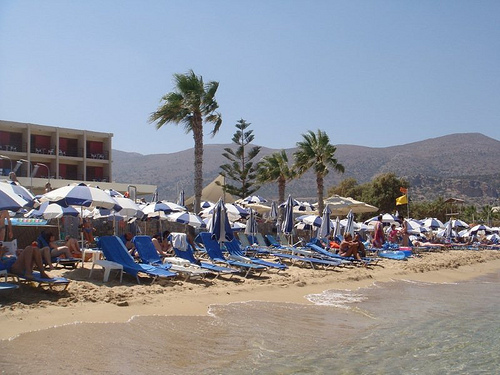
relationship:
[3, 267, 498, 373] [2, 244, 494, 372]
water on beach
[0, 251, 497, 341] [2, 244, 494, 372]
sand on beach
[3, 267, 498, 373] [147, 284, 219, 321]
water near sand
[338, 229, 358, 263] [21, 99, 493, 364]
person on beach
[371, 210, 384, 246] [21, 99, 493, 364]
person on beach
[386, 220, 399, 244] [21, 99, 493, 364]
person on beach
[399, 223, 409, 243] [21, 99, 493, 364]
person on beach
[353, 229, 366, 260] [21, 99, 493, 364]
person on beach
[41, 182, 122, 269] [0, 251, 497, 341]
umbrellas on sand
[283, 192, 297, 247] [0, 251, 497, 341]
umbrellas on sand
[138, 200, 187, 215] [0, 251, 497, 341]
umbrella on sand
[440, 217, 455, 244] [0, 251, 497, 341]
umbrellas on sand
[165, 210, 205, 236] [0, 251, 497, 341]
umbrellas on sand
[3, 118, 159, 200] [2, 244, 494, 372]
building on beach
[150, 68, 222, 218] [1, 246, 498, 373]
tree on sand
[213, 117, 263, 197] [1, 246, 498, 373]
tree on sand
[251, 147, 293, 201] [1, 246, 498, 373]
tree on sand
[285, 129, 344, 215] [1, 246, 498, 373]
tree on sand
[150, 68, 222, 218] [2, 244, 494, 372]
tree on beach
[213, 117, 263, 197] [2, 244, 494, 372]
tree on beach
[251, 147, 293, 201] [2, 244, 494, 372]
tree on beach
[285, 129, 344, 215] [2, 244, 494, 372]
tree on beach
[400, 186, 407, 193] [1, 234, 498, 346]
flag on beach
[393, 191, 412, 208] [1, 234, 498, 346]
flag on beach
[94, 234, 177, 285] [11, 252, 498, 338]
beach chair on beach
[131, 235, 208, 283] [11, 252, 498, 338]
beach chair on beach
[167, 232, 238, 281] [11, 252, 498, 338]
beach chair on beach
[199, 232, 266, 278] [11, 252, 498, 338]
beach chair on beach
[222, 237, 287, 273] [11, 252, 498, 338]
beach chair on beach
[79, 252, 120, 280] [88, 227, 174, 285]
table next to chair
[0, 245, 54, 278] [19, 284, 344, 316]
person on beach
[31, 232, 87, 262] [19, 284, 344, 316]
person on beach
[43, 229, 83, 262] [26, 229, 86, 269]
person lying on chair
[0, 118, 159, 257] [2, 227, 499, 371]
building on beach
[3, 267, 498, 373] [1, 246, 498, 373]
water on sand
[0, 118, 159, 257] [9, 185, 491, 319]
building near beach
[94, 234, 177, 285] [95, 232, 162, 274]
beach chair covered by towel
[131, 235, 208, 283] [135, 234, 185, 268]
beach chair covered by towel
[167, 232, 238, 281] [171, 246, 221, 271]
beach chair covered by towel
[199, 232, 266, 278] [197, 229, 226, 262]
beach chair covered by towel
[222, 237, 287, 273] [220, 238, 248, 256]
beach chair covered by towel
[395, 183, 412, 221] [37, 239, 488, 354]
flag ay beach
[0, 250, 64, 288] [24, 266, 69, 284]
person laying in chair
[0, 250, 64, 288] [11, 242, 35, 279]
person has leg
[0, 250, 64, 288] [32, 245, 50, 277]
person has leg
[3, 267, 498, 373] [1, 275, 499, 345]
water has foam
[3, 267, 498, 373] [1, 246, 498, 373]
water lapping sand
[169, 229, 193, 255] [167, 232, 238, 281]
towel on beach chair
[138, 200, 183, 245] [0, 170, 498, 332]
umbrella on beach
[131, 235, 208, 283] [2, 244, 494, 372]
beach chair on beach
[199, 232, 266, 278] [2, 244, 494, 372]
beach chair on beach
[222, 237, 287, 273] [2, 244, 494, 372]
beach chair on beach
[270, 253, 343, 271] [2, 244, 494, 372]
beach chair on beach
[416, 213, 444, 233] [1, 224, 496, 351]
umbrella on beach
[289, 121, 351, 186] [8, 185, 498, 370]
tree in beach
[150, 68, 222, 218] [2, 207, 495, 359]
tree in beach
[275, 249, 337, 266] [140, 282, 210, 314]
beach chair on sand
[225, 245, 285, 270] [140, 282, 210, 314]
beach chair on sand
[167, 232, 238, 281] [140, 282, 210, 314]
beach chair on sand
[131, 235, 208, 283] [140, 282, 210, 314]
beach chair on sand